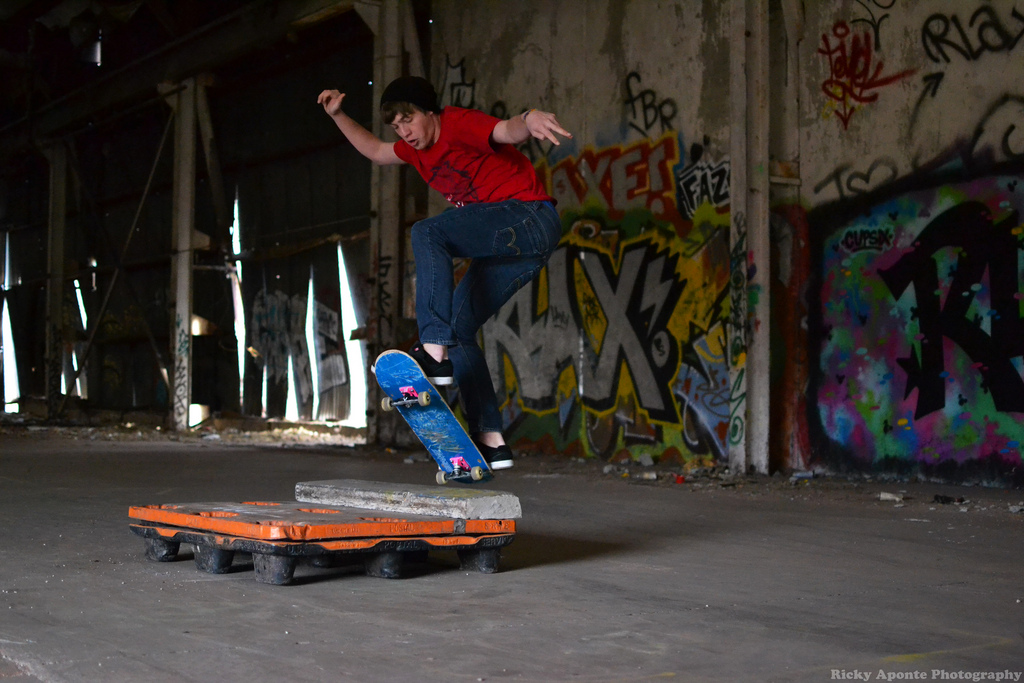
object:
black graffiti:
[905, 241, 950, 424]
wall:
[569, 20, 971, 492]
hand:
[522, 108, 576, 146]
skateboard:
[360, 351, 503, 486]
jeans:
[413, 202, 552, 417]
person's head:
[376, 77, 447, 152]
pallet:
[131, 465, 548, 604]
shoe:
[369, 342, 456, 391]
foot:
[369, 330, 461, 388]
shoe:
[434, 437, 514, 472]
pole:
[161, 61, 205, 440]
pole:
[30, 108, 91, 411]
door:
[36, 99, 238, 449]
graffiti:
[414, 138, 1011, 501]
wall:
[381, 0, 1021, 498]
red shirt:
[384, 105, 554, 212]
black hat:
[373, 74, 440, 111]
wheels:
[250, 549, 298, 586]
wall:
[0, 1, 1005, 513]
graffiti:
[774, 77, 1020, 499]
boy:
[309, 68, 569, 479]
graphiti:
[477, 194, 764, 469]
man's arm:
[454, 105, 574, 147]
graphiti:
[232, 281, 385, 413]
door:
[169, 68, 401, 440]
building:
[0, 0, 1008, 508]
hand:
[314, 88, 347, 116]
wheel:
[415, 389, 433, 407]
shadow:
[213, 484, 754, 580]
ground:
[6, 418, 1017, 678]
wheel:
[377, 396, 396, 414]